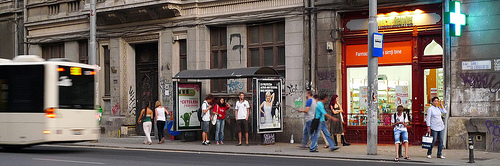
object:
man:
[308, 93, 341, 153]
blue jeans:
[392, 128, 410, 145]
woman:
[424, 96, 447, 158]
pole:
[366, 0, 376, 155]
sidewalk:
[32, 134, 499, 165]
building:
[0, 0, 500, 153]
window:
[271, 22, 284, 45]